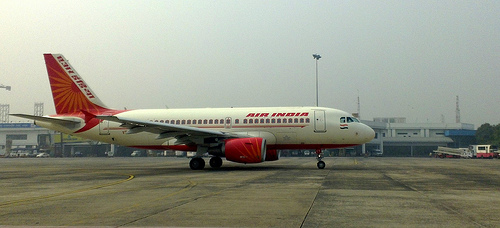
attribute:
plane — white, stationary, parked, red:
[10, 52, 377, 170]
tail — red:
[45, 54, 110, 114]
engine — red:
[225, 137, 268, 163]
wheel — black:
[316, 161, 326, 167]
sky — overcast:
[1, 0, 499, 123]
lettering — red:
[245, 112, 310, 118]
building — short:
[0, 116, 475, 158]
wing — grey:
[89, 114, 239, 151]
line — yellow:
[1, 170, 135, 201]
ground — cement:
[5, 158, 500, 227]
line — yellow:
[54, 175, 200, 227]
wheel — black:
[188, 156, 205, 171]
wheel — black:
[209, 156, 223, 169]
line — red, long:
[102, 123, 311, 133]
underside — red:
[122, 141, 362, 154]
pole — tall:
[314, 52, 320, 105]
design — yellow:
[48, 65, 98, 113]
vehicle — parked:
[37, 150, 51, 156]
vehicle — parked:
[24, 148, 32, 156]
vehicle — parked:
[11, 148, 19, 158]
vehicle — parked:
[473, 144, 491, 156]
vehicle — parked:
[431, 145, 473, 159]